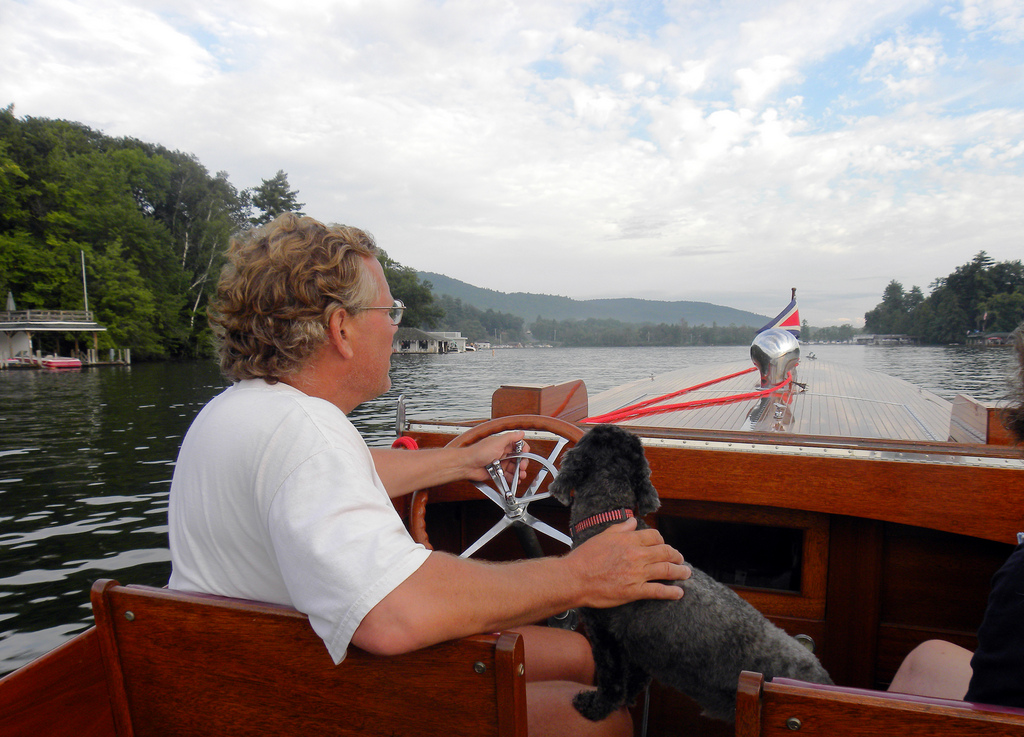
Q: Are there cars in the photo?
A: No, there are no cars.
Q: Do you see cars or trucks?
A: No, there are no cars or trucks.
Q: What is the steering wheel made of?
A: The steering wheel is made of wood.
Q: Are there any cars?
A: No, there are no cars.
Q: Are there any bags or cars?
A: No, there are no cars or bags.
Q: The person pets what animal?
A: The person pets the dog.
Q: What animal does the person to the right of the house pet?
A: The person pets the dog.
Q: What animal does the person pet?
A: The person pets the dog.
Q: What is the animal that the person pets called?
A: The animal is a dog.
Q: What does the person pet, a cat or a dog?
A: The person pets a dog.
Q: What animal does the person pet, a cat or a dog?
A: The person pets a dog.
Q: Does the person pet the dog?
A: Yes, the person pets the dog.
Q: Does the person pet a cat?
A: No, the person pets the dog.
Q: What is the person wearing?
A: The person is wearing a shirt.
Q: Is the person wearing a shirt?
A: Yes, the person is wearing a shirt.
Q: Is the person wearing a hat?
A: No, the person is wearing a shirt.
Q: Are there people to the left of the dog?
A: Yes, there is a person to the left of the dog.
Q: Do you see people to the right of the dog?
A: No, the person is to the left of the dog.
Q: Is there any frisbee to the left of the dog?
A: No, there is a person to the left of the dog.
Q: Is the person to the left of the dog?
A: Yes, the person is to the left of the dog.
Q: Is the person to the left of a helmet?
A: No, the person is to the left of the dog.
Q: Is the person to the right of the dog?
A: No, the person is to the left of the dog.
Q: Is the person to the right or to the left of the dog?
A: The person is to the left of the dog.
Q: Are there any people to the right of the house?
A: Yes, there is a person to the right of the house.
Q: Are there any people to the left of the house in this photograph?
A: No, the person is to the right of the house.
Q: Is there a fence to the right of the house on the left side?
A: No, there is a person to the right of the house.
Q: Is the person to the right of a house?
A: Yes, the person is to the right of a house.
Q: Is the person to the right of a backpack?
A: No, the person is to the right of a house.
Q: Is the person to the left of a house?
A: No, the person is to the right of a house.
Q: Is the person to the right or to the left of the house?
A: The person is to the right of the house.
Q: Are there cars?
A: No, there are no cars.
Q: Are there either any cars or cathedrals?
A: No, there are no cars or cathedrals.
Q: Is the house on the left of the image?
A: Yes, the house is on the left of the image.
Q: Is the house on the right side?
A: No, the house is on the left of the image.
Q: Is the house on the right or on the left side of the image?
A: The house is on the left of the image.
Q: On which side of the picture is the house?
A: The house is on the left of the image.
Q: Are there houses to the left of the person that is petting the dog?
A: Yes, there is a house to the left of the person.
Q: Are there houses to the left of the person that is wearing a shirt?
A: Yes, there is a house to the left of the person.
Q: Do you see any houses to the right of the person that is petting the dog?
A: No, the house is to the left of the person.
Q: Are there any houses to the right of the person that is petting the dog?
A: No, the house is to the left of the person.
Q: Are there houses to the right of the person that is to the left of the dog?
A: No, the house is to the left of the person.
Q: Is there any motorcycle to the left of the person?
A: No, there is a house to the left of the person.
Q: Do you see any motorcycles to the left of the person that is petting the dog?
A: No, there is a house to the left of the person.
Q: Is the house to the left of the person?
A: Yes, the house is to the left of the person.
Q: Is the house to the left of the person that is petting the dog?
A: Yes, the house is to the left of the person.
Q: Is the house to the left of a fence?
A: No, the house is to the left of the person.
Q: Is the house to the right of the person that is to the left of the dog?
A: No, the house is to the left of the person.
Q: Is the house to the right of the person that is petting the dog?
A: No, the house is to the left of the person.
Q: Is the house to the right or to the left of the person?
A: The house is to the left of the person.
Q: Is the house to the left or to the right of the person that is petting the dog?
A: The house is to the left of the person.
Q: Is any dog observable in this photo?
A: Yes, there is a dog.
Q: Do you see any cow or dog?
A: Yes, there is a dog.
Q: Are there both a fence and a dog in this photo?
A: No, there is a dog but no fences.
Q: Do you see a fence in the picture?
A: No, there are no fences.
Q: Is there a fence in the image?
A: No, there are no fences.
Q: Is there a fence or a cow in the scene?
A: No, there are no fences or cows.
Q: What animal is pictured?
A: The animal is a dog.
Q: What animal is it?
A: The animal is a dog.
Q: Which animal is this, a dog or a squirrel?
A: This is a dog.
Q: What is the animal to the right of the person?
A: The animal is a dog.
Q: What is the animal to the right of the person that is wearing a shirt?
A: The animal is a dog.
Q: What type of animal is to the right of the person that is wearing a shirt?
A: The animal is a dog.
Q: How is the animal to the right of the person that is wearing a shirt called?
A: The animal is a dog.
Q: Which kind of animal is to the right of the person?
A: The animal is a dog.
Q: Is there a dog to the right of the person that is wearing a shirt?
A: Yes, there is a dog to the right of the person.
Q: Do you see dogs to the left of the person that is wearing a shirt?
A: No, the dog is to the right of the person.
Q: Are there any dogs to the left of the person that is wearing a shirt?
A: No, the dog is to the right of the person.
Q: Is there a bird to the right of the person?
A: No, there is a dog to the right of the person.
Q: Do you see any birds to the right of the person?
A: No, there is a dog to the right of the person.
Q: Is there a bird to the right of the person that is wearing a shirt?
A: No, there is a dog to the right of the person.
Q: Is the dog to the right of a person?
A: Yes, the dog is to the right of a person.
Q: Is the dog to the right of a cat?
A: No, the dog is to the right of a person.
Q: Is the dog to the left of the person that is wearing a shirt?
A: No, the dog is to the right of the person.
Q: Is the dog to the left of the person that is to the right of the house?
A: No, the dog is to the right of the person.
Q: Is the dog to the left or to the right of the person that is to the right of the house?
A: The dog is to the right of the person.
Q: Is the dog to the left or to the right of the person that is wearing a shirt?
A: The dog is to the right of the person.